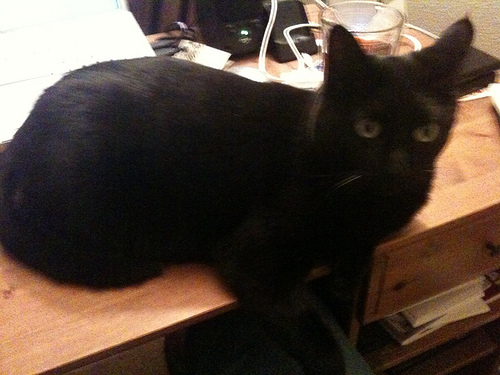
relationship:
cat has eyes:
[2, 15, 478, 337] [352, 119, 442, 150]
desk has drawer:
[0, 2, 497, 372] [358, 199, 499, 329]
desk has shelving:
[0, 2, 497, 372] [353, 272, 499, 371]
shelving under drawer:
[353, 272, 499, 371] [373, 200, 497, 313]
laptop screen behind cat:
[0, 5, 161, 145] [2, 15, 478, 337]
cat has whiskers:
[0, 15, 473, 375] [321, 171, 363, 193]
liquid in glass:
[357, 28, 394, 63] [317, 0, 403, 65]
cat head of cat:
[318, 22, 473, 199] [0, 15, 473, 375]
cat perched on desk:
[0, 15, 473, 375] [2, 127, 472, 373]